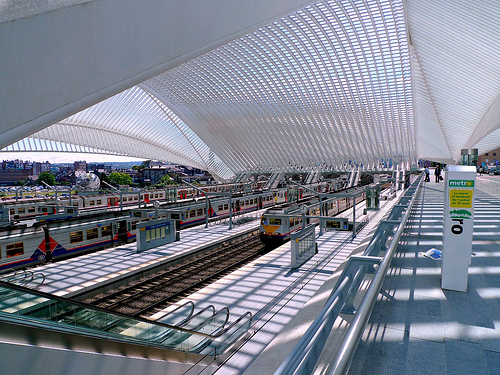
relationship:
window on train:
[69, 230, 83, 243] [2, 173, 352, 267]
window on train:
[97, 224, 116, 236] [2, 173, 352, 267]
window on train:
[8, 237, 23, 257] [2, 173, 352, 267]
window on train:
[86, 227, 99, 240] [2, 173, 352, 267]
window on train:
[101, 224, 113, 237] [2, 173, 352, 267]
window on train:
[16, 203, 29, 214] [5, 172, 305, 222]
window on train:
[17, 207, 25, 214] [3, 171, 276, 226]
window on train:
[33, 203, 48, 213] [0, 178, 279, 227]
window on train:
[89, 200, 95, 205] [3, 171, 276, 226]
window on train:
[106, 191, 118, 207] [3, 169, 272, 221]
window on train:
[186, 205, 196, 216] [2, 173, 352, 267]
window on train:
[0, 176, 347, 270] [86, 224, 103, 241]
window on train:
[101, 224, 113, 237] [4, 180, 343, 279]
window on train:
[178, 209, 191, 222] [3, 169, 368, 269]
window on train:
[194, 205, 204, 214] [2, 173, 352, 267]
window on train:
[154, 190, 161, 207] [3, 171, 276, 226]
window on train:
[146, 193, 151, 203] [3, 171, 276, 226]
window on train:
[128, 191, 136, 201] [3, 171, 276, 226]